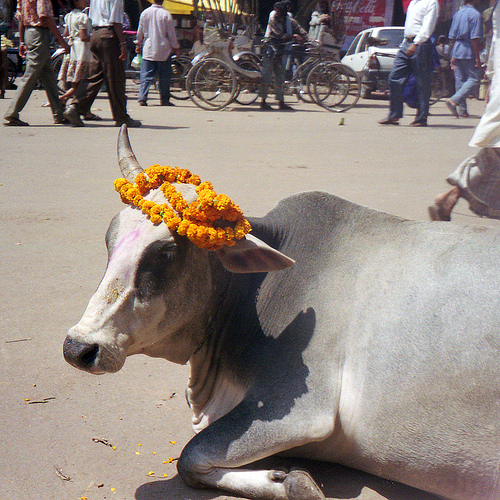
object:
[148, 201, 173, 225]
flower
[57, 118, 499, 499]
animal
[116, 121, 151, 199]
horn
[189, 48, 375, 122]
bicycle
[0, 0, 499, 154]
background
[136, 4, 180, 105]
people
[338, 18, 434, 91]
car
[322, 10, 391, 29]
advertising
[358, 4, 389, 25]
coke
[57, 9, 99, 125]
woman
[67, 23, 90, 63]
dress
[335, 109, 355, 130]
flower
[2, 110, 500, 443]
ground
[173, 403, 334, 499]
leg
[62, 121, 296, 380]
head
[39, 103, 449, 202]
street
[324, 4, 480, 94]
shop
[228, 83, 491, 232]
road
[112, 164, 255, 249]
wreath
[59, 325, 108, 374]
nose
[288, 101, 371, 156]
debris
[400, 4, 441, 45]
shirt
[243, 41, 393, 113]
bike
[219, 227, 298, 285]
ear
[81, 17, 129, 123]
pants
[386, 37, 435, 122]
jeans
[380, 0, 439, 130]
man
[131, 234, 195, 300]
eyes